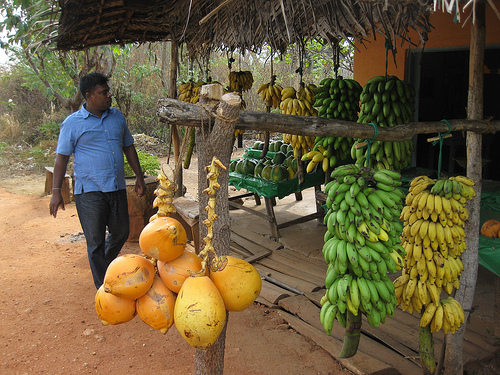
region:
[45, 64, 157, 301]
Indian man looking at food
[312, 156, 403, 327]
Green stack of bananas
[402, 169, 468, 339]
This stack is yellow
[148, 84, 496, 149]
Horizontal beam of wood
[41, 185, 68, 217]
Man's left hand is brown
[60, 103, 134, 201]
Shirt is blue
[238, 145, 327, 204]
Table with green tarp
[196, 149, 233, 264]
Vine of fruits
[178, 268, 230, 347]
Large yellow fruit is round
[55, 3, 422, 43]
Thatched brown roof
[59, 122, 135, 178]
the shirt is light blue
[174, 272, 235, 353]
the fruit is yellow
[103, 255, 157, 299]
the fruit is orange in color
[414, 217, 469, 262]
the banana's are yellow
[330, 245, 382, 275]
the banana's are green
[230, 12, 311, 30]
the roof is made up of branches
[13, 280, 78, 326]
the dirt is brown in color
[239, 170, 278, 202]
the plastic is green in color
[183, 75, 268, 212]
the cut tree still has bark on it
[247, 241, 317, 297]
the floor is made up of cut trees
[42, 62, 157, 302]
a man wears a blue shirt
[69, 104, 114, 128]
collar of blue shirt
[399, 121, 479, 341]
bananas are yellow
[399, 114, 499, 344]
bananas hang from a trunk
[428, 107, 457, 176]
green hook to hang bananas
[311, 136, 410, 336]
handles of bananas are green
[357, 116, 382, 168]
hook hanging the bananas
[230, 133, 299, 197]
papayas on a stand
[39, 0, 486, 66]
roof of store is made of straw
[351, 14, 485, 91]
wall of store is orange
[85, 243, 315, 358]
the coconut is yellow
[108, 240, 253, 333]
the coconut is yellow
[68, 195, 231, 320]
the coconut is yellow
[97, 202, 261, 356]
big orange fruit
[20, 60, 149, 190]
man wearing a blue shirt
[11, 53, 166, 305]
a man is walking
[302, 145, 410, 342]
a bushel of green bananas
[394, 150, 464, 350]
a bushel of yellow bananas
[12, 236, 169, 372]
the dirt is brown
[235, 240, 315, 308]
the floor is made of wood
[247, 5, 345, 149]
bananas are hanging from the ceiling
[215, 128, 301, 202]
other fruits are displayed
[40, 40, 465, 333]
the fruit is being sold